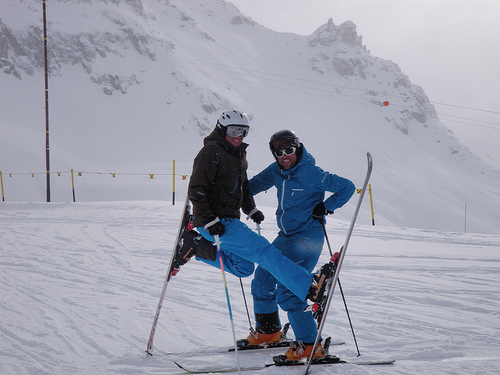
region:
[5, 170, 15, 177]
small yellow colored flag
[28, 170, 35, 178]
small yellow colored flag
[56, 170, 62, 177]
small yellow colored flag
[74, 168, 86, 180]
small yellow colored flag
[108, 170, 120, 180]
small yellow colored flag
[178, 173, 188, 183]
small yellow colored flag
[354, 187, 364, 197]
small yellow colored flag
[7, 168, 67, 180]
small yellow colored flags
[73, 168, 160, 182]
small yellow colored flags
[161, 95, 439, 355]
two people that are skiing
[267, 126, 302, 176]
the head of an adult man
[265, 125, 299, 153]
the hair of an adult man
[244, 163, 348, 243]
the jacket of an adult man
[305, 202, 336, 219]
the gloves of an adult man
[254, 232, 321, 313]
the ski pants of an adult man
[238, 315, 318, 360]
the ski boots of an adult man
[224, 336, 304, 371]
the black skis of an adult man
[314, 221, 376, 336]
a pair of black ski sticks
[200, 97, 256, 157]
Skier wearing white helmet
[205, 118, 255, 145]
Skier wearing snow goggles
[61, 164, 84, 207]
yellow painted pole in the snow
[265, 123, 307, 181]
Skier wearing dark helmet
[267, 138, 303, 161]
Skier wearing white glasses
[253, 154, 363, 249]
Skier wearing a blue jacket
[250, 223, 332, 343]
Skier wearing blue pants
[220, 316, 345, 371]
skier wearing ski boots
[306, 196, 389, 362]
skier holding a ski pole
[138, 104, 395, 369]
Skiers on the snow.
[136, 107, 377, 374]
Lady holding herself up by skis.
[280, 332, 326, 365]
Orange boot on foot.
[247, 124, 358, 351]
blue outfit on man.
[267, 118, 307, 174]
black helmet on the man.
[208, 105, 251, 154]
white helmet on woman.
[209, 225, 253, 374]
ski pole in hand.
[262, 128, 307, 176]
White goggles on man.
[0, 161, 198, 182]
Rope in the background.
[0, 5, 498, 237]
Mountain in the background.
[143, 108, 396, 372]
Two skiers on a snowy slope.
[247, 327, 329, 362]
Two orange ski boots.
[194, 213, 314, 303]
A pair of blue ski pants.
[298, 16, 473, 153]
A rocky outcropping covered in snow.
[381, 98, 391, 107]
A red ball wire guide.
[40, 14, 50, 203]
A pole on the side of a ski slope.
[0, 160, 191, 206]
A flagged fence on the side of a ski slope.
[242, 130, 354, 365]
A man standing on his skis.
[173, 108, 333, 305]
A man balancing on his skis above the ground.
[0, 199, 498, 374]
A snow covered ski slope.